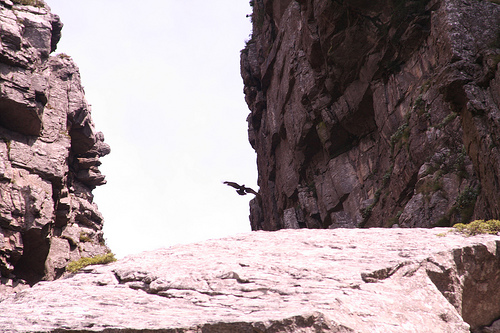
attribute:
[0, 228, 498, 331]
rock — light brown, gray, brown, large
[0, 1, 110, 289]
rock — rough, light brown, high, sharp, brown, tall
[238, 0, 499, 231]
rock — rough, high, shadowy, brown, large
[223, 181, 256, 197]
bird — black, flying, gliding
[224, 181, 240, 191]
wing — spread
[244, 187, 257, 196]
wing — spread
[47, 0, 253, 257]
sky — white, clear, cloudy, overcast, light grey, grey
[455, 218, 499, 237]
grass — green, short, sparce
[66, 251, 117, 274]
grass — green, short, sparce